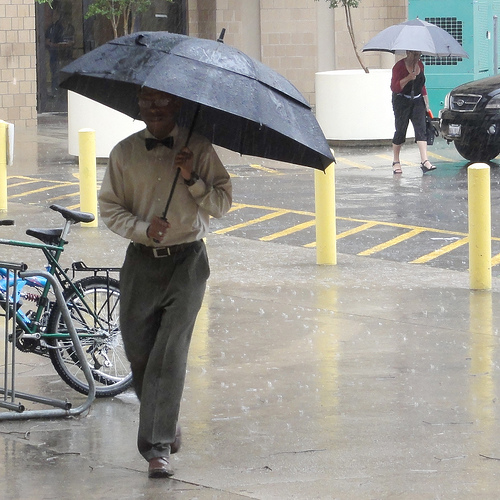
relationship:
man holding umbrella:
[51, 23, 248, 483] [68, 12, 337, 194]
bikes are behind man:
[1, 234, 83, 367] [51, 23, 248, 483]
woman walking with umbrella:
[377, 57, 435, 169] [68, 12, 337, 194]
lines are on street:
[229, 200, 302, 243] [263, 223, 327, 272]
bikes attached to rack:
[1, 234, 83, 367] [5, 378, 52, 412]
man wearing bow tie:
[51, 23, 248, 483] [134, 135, 170, 152]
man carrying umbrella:
[51, 23, 248, 483] [68, 12, 337, 194]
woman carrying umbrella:
[377, 57, 435, 169] [68, 12, 337, 194]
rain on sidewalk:
[5, 6, 484, 175] [266, 267, 300, 290]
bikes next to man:
[1, 234, 83, 367] [51, 23, 248, 483]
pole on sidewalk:
[58, 125, 95, 193] [266, 267, 300, 290]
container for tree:
[55, 103, 108, 143] [100, 8, 125, 34]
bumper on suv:
[440, 121, 467, 143] [435, 68, 500, 168]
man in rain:
[51, 23, 248, 483] [5, 6, 484, 175]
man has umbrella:
[51, 23, 248, 483] [68, 12, 337, 194]